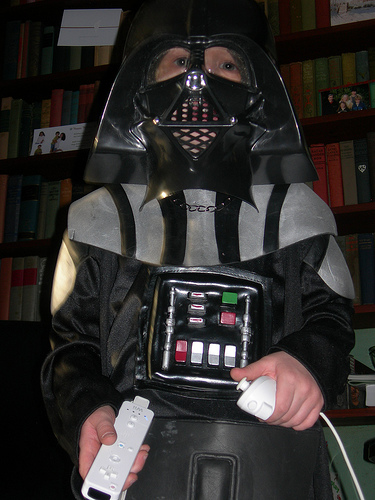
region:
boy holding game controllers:
[19, 11, 373, 492]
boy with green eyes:
[70, 29, 325, 194]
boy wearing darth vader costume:
[29, 28, 352, 494]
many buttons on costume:
[139, 252, 279, 388]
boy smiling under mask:
[88, 16, 328, 218]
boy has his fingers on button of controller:
[209, 347, 349, 461]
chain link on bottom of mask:
[94, 129, 262, 219]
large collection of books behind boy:
[9, 12, 369, 208]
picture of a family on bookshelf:
[317, 81, 373, 116]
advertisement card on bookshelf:
[24, 118, 105, 164]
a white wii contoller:
[70, 383, 169, 498]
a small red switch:
[162, 331, 191, 378]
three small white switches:
[188, 341, 238, 376]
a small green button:
[213, 286, 240, 310]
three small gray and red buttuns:
[186, 285, 210, 333]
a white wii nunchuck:
[202, 371, 350, 444]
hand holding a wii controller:
[66, 388, 153, 498]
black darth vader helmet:
[65, 12, 327, 202]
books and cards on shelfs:
[0, 1, 100, 298]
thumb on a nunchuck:
[212, 344, 278, 442]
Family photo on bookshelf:
[316, 81, 370, 117]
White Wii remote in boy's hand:
[77, 385, 155, 495]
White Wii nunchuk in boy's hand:
[225, 350, 329, 423]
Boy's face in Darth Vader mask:
[125, 19, 264, 160]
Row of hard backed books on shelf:
[307, 133, 371, 215]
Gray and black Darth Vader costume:
[100, 208, 296, 418]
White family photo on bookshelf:
[14, 121, 77, 159]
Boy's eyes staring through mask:
[166, 43, 238, 77]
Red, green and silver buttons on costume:
[165, 280, 239, 367]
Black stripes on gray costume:
[103, 185, 279, 248]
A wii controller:
[85, 391, 158, 498]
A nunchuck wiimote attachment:
[225, 373, 333, 445]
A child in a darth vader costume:
[41, 9, 353, 499]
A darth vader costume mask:
[88, 1, 324, 177]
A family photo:
[319, 86, 372, 115]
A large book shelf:
[10, 21, 374, 486]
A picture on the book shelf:
[30, 122, 97, 160]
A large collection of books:
[12, 10, 373, 461]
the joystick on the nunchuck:
[225, 368, 254, 389]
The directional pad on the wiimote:
[96, 465, 122, 480]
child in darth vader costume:
[50, 16, 357, 337]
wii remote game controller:
[70, 391, 162, 497]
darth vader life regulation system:
[155, 275, 273, 388]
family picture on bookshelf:
[319, 78, 374, 119]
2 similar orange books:
[304, 142, 353, 201]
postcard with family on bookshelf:
[22, 118, 91, 154]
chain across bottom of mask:
[156, 192, 258, 214]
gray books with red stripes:
[5, 256, 50, 319]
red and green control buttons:
[214, 291, 246, 340]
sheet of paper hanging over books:
[55, 3, 134, 63]